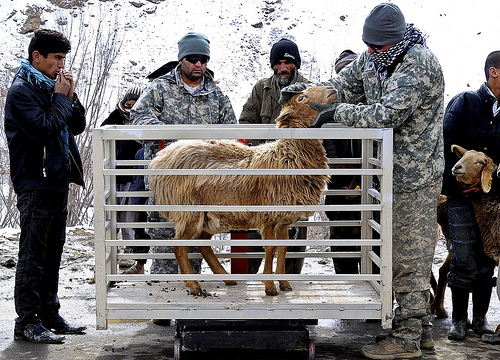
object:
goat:
[140, 79, 344, 298]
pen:
[91, 123, 394, 330]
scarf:
[9, 60, 72, 169]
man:
[277, 1, 449, 359]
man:
[121, 33, 241, 327]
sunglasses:
[185, 54, 210, 65]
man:
[240, 32, 316, 276]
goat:
[447, 143, 500, 267]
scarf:
[361, 23, 421, 79]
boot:
[356, 337, 425, 359]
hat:
[265, 37, 303, 72]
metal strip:
[103, 169, 383, 177]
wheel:
[169, 337, 183, 360]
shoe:
[12, 326, 69, 350]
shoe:
[360, 334, 424, 359]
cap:
[358, 0, 410, 48]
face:
[181, 57, 210, 80]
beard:
[270, 67, 302, 85]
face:
[268, 59, 298, 87]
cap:
[175, 31, 212, 62]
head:
[447, 142, 498, 195]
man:
[4, 21, 90, 349]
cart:
[168, 319, 319, 359]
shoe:
[38, 314, 88, 337]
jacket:
[236, 68, 314, 149]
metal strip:
[104, 202, 381, 218]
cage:
[82, 117, 399, 332]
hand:
[51, 71, 75, 96]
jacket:
[293, 43, 452, 199]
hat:
[359, 0, 410, 47]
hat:
[116, 86, 144, 104]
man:
[441, 50, 500, 343]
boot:
[442, 282, 473, 342]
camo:
[395, 70, 424, 107]